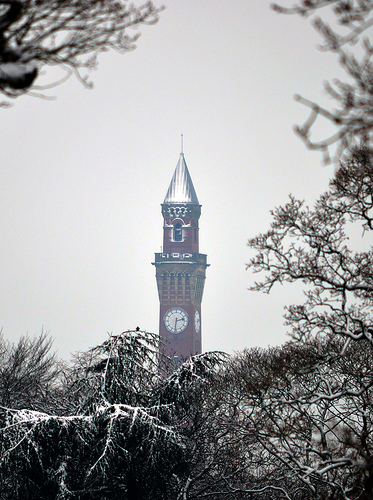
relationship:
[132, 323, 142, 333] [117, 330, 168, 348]
bird sitting on branch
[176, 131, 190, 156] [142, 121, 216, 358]
spire on top of tower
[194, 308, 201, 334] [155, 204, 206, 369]
clock on brick building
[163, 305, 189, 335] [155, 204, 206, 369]
clock on brick building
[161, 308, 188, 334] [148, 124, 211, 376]
clock front building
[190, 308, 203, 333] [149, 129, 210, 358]
clock side building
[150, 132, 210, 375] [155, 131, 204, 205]
brick building has spire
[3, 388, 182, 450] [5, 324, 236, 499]
snow on branches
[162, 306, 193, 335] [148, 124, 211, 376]
clock hands on building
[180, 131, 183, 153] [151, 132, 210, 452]
bar top building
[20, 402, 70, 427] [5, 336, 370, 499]
snow covering trees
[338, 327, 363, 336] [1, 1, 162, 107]
snow covering trees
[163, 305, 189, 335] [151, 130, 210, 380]
clock on tower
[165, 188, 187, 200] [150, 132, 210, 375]
snow on brick building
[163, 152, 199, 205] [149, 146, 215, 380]
roof on tower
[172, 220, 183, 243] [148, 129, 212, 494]
window on tower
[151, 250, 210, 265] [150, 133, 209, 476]
balcony on tower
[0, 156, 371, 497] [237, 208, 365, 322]
snow covering branch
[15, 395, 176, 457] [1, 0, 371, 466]
snow on branches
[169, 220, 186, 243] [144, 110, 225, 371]
window on tower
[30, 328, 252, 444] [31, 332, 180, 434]
snow on trees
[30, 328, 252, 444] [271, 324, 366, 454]
snow on trees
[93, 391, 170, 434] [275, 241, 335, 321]
snow covered tree branches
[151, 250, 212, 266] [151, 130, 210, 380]
balcony going around tower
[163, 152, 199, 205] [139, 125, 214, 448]
roof on building